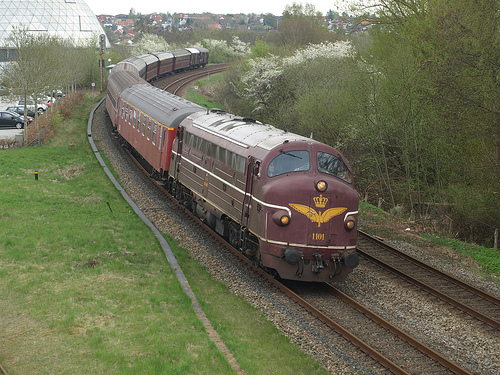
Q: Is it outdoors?
A: Yes, it is outdoors.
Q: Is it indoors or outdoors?
A: It is outdoors.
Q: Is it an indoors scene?
A: No, it is outdoors.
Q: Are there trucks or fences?
A: No, there are no fences or trucks.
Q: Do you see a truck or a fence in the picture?
A: No, there are no fences or trucks.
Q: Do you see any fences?
A: No, there are no fences.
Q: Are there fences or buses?
A: No, there are no fences or buses.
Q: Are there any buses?
A: No, there are no buses.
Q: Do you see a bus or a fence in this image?
A: No, there are no buses or fences.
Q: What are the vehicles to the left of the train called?
A: The vehicles are cars.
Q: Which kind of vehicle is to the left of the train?
A: The vehicles are cars.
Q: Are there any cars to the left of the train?
A: Yes, there are cars to the left of the train.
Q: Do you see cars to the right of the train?
A: No, the cars are to the left of the train.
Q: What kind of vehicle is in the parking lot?
A: The vehicles are cars.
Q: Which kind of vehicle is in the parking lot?
A: The vehicles are cars.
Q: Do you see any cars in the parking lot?
A: Yes, there are cars in the parking lot.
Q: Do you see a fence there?
A: No, there are no fences.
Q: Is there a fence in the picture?
A: No, there are no fences.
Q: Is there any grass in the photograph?
A: Yes, there is grass.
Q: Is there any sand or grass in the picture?
A: Yes, there is grass.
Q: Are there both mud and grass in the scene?
A: No, there is grass but no mud.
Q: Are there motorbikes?
A: No, there are no motorbikes.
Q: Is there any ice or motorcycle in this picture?
A: No, there are no motorcycles or ice.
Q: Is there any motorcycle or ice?
A: No, there are no motorcycles or ice.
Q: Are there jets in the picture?
A: No, there are no jets.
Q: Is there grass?
A: Yes, there is grass.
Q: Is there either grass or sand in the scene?
A: Yes, there is grass.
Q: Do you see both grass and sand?
A: No, there is grass but no sand.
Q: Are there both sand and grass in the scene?
A: No, there is grass but no sand.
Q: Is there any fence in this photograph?
A: No, there are no fences.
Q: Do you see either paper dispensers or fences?
A: No, there are no fences or paper dispensers.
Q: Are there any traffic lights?
A: No, there are no traffic lights.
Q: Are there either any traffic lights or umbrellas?
A: No, there are no traffic lights or umbrellas.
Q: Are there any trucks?
A: No, there are no trucks.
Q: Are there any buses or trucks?
A: No, there are no trucks or buses.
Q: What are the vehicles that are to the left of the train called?
A: The vehicles are cars.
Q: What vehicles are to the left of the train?
A: The vehicles are cars.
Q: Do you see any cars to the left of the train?
A: Yes, there are cars to the left of the train.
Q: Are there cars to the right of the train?
A: No, the cars are to the left of the train.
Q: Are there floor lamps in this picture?
A: No, there are no floor lamps.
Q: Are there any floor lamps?
A: No, there are no floor lamps.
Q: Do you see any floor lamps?
A: No, there are no floor lamps.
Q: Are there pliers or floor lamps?
A: No, there are no floor lamps or pliers.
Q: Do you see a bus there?
A: No, there are no buses.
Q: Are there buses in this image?
A: No, there are no buses.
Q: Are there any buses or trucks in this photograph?
A: No, there are no buses or trucks.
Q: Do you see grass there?
A: Yes, there is grass.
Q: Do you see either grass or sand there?
A: Yes, there is grass.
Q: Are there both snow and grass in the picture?
A: No, there is grass but no snow.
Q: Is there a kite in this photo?
A: No, there are no kites.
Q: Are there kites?
A: No, there are no kites.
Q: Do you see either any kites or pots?
A: No, there are no kites or pots.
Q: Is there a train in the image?
A: Yes, there is a train.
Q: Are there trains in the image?
A: Yes, there is a train.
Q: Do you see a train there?
A: Yes, there is a train.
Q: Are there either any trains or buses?
A: Yes, there is a train.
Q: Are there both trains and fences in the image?
A: No, there is a train but no fences.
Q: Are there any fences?
A: No, there are no fences.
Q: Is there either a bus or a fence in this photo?
A: No, there are no fences or buses.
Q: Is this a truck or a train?
A: This is a train.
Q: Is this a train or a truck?
A: This is a train.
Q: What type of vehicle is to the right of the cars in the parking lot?
A: The vehicle is a train.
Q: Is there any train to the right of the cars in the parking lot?
A: Yes, there is a train to the right of the cars.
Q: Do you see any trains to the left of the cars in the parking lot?
A: No, the train is to the right of the cars.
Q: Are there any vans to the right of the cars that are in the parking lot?
A: No, there is a train to the right of the cars.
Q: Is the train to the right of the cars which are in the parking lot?
A: Yes, the train is to the right of the cars.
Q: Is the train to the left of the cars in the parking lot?
A: No, the train is to the right of the cars.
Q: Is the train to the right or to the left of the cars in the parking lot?
A: The train is to the right of the cars.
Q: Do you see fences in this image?
A: No, there are no fences.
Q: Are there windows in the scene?
A: Yes, there is a window.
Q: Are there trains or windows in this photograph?
A: Yes, there is a window.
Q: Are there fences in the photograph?
A: No, there are no fences.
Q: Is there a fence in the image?
A: No, there are no fences.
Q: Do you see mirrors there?
A: No, there are no mirrors.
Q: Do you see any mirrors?
A: No, there are no mirrors.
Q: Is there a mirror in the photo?
A: No, there are no mirrors.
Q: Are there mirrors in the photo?
A: No, there are no mirrors.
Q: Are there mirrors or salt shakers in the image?
A: No, there are no mirrors or salt shakers.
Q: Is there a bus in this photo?
A: No, there are no buses.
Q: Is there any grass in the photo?
A: Yes, there is grass.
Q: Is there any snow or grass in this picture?
A: Yes, there is grass.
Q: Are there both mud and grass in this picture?
A: No, there is grass but no mud.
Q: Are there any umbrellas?
A: No, there are no umbrellas.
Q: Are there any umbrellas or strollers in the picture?
A: No, there are no umbrellas or strollers.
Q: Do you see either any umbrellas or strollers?
A: No, there are no umbrellas or strollers.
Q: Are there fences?
A: No, there are no fences.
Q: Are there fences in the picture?
A: No, there are no fences.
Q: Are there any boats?
A: No, there are no boats.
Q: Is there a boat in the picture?
A: No, there are no boats.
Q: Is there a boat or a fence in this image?
A: No, there are no boats or fences.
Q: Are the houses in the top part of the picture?
A: Yes, the houses are in the top of the image.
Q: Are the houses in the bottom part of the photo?
A: No, the houses are in the top of the image.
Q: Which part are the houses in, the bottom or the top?
A: The houses are in the top of the image.